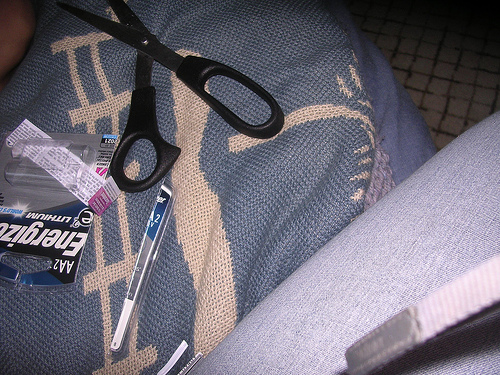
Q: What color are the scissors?
A: Black.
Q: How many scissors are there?
A: One.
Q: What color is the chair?
A: Blue.